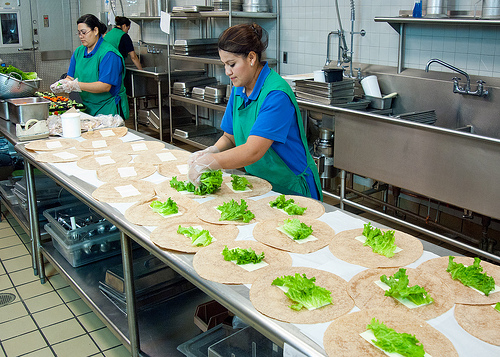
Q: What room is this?
A: An industrial kitchen.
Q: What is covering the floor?
A: White tile.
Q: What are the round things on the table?
A: Tortillas.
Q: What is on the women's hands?
A: Plastic gloves.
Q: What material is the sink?
A: Stainless steel.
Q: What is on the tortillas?
A: Lettuce.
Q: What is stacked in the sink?
A: Dishes.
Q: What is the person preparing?
A: Salad.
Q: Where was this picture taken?
A: Kitchen.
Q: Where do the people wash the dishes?
A: Sink.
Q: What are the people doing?
A: Prepping.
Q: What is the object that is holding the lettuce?
A: Tortilla.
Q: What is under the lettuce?
A: Cheese.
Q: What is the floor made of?
A: Tile.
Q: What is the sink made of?
A: Metal.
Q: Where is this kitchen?
A: Restaurant.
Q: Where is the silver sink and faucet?
A: The sink is behind the woman.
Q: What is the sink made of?
A: The sink is made of stainless steel.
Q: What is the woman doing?
A: The woman is preparing a dish.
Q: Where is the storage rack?
A: The metal storage rack is behind the woman.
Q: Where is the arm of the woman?
A: The arm is in front of the woman.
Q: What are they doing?
A: Preparing food.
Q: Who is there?
A: 2 women.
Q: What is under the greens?
A: Cheese.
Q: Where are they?
A: Kitchen.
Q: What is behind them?
A: Sinks.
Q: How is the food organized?
A: Aligned.